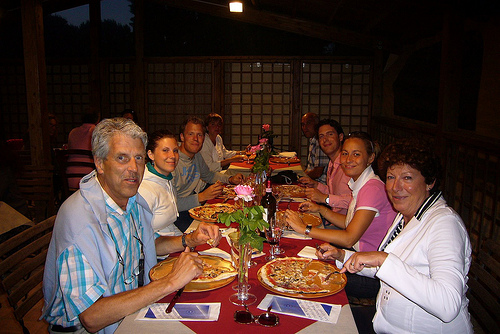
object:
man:
[39, 115, 224, 333]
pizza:
[186, 259, 235, 283]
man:
[166, 113, 246, 215]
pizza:
[214, 182, 247, 197]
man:
[294, 108, 333, 184]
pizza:
[275, 151, 298, 166]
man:
[297, 120, 354, 216]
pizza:
[274, 184, 312, 197]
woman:
[134, 131, 185, 259]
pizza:
[186, 202, 240, 222]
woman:
[198, 113, 250, 175]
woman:
[284, 130, 399, 299]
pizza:
[275, 207, 321, 229]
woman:
[313, 140, 477, 333]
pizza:
[259, 256, 347, 295]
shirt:
[43, 174, 164, 328]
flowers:
[216, 180, 271, 284]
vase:
[228, 242, 257, 306]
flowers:
[249, 137, 274, 184]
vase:
[253, 169, 266, 206]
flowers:
[260, 123, 274, 148]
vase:
[266, 141, 271, 161]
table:
[112, 151, 362, 334]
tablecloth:
[153, 230, 350, 333]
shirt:
[343, 164, 398, 254]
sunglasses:
[232, 308, 280, 328]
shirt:
[309, 154, 359, 211]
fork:
[324, 270, 355, 281]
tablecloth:
[206, 193, 313, 231]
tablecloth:
[229, 155, 300, 172]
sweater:
[41, 169, 164, 333]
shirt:
[194, 131, 235, 172]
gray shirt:
[164, 150, 235, 213]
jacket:
[334, 190, 471, 333]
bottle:
[259, 179, 279, 243]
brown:
[265, 196, 271, 205]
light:
[226, 0, 245, 17]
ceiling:
[193, 0, 498, 11]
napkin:
[256, 292, 342, 325]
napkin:
[133, 302, 222, 323]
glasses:
[114, 233, 146, 284]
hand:
[335, 246, 387, 278]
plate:
[148, 253, 240, 294]